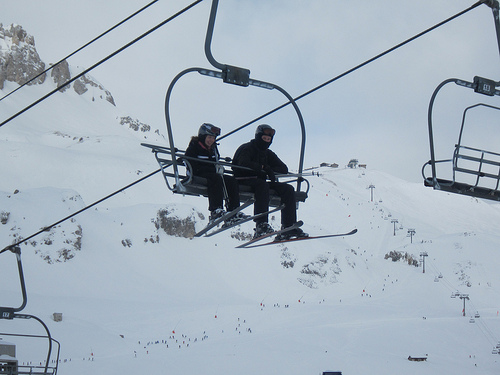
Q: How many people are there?
A: Two.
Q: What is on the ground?
A: Snow.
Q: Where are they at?
A: On a ski lift.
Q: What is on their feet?
A: Skiis.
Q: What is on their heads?
A: Helmets.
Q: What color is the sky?
A: White.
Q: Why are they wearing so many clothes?
A: Cold outside.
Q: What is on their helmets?
A: Goggles.